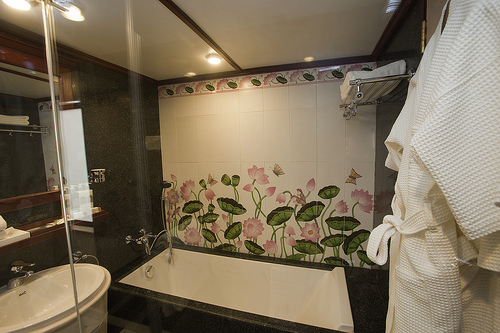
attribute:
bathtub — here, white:
[122, 224, 382, 313]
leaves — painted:
[218, 197, 265, 241]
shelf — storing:
[333, 62, 410, 101]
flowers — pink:
[171, 168, 232, 213]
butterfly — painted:
[263, 157, 316, 194]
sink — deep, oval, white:
[17, 265, 129, 332]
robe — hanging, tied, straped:
[396, 30, 479, 278]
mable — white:
[238, 273, 305, 295]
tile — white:
[186, 142, 363, 222]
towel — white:
[362, 60, 403, 85]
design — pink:
[165, 153, 412, 249]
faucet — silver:
[124, 220, 153, 259]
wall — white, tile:
[167, 93, 372, 179]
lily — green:
[281, 233, 357, 276]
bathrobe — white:
[437, 47, 487, 159]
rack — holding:
[338, 90, 416, 134]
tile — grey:
[141, 282, 199, 313]